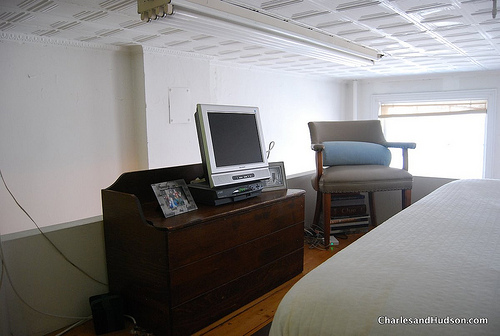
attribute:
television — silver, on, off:
[189, 103, 272, 190]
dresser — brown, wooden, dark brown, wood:
[100, 161, 305, 335]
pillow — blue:
[314, 140, 392, 167]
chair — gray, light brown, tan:
[305, 117, 417, 250]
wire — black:
[1, 172, 110, 288]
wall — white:
[1, 32, 347, 335]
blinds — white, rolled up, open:
[375, 99, 487, 118]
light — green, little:
[329, 239, 335, 248]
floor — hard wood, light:
[39, 232, 371, 335]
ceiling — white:
[0, 0, 499, 81]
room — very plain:
[0, 1, 498, 335]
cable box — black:
[190, 178, 265, 207]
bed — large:
[267, 176, 498, 335]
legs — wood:
[310, 189, 412, 250]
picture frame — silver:
[151, 177, 198, 220]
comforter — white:
[263, 177, 499, 334]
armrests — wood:
[311, 140, 417, 175]